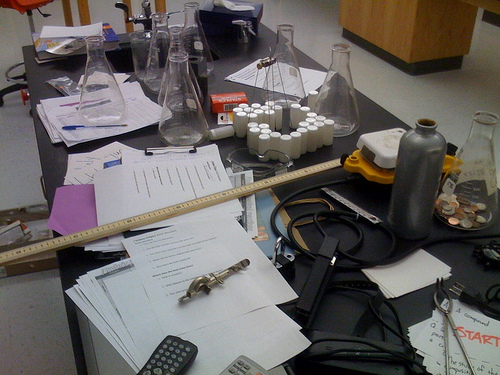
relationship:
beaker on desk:
[435, 111, 499, 231] [16, 0, 496, 374]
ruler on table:
[9, 159, 346, 270] [37, 156, 364, 307]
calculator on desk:
[135, 334, 200, 375] [16, 0, 496, 374]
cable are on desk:
[270, 177, 428, 374] [16, 0, 496, 374]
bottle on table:
[387, 118, 448, 241] [51, 91, 469, 354]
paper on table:
[25, 159, 134, 265] [8, 39, 370, 373]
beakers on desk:
[312, 43, 361, 138] [16, 0, 496, 374]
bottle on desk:
[387, 118, 448, 241] [16, 0, 496, 374]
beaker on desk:
[158, 51, 210, 146] [16, 0, 496, 374]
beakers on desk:
[78, 35, 125, 127] [16, 0, 496, 374]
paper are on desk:
[407, 297, 499, 374] [16, 0, 496, 374]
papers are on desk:
[361, 248, 454, 299] [16, 0, 496, 374]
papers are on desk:
[62, 207, 312, 372] [16, 0, 496, 374]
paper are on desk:
[45, 141, 258, 254] [16, 0, 496, 374]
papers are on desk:
[36, 81, 175, 148] [16, 0, 496, 374]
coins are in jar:
[435, 192, 485, 225] [435, 113, 493, 230]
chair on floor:
[2, 0, 64, 110] [4, 10, 40, 225]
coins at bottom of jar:
[435, 192, 487, 229] [434, 106, 496, 236]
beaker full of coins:
[429, 104, 499, 235] [442, 202, 482, 224]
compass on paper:
[177, 257, 250, 303] [121, 239, 224, 273]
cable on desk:
[270, 177, 428, 374] [16, 3, 498, 374]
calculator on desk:
[144, 323, 204, 373] [21, 277, 129, 368]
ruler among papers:
[0, 157, 342, 266] [44, 140, 311, 374]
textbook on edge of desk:
[33, 19, 105, 54] [16, 0, 496, 374]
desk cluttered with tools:
[16, 0, 496, 374] [29, 31, 498, 373]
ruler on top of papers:
[9, 159, 346, 270] [33, 84, 316, 371]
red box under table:
[217, 84, 257, 113] [54, 7, 491, 372]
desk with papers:
[16, 3, 498, 374] [122, 210, 297, 335]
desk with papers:
[16, 3, 498, 374] [96, 144, 243, 226]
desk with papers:
[16, 3, 498, 374] [363, 248, 450, 300]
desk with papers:
[16, 3, 498, 374] [37, 82, 173, 151]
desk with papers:
[16, 3, 498, 374] [226, 60, 338, 98]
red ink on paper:
[440, 316, 498, 350] [407, 297, 499, 374]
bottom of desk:
[323, 1, 473, 77] [335, 2, 479, 75]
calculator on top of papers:
[135, 334, 200, 375] [59, 207, 313, 372]